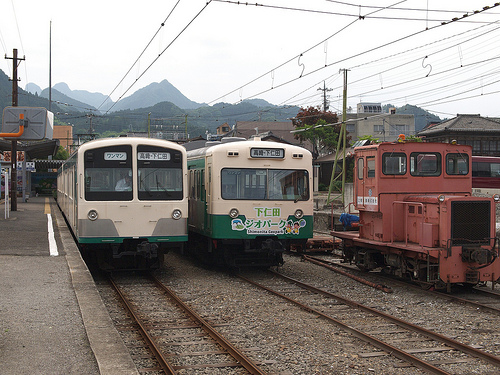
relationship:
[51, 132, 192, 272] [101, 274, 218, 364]
rail car on tracks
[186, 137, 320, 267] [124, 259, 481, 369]
rail car on tracks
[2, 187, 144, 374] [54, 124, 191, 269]
platform beside train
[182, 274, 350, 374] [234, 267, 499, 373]
gravel beside tracks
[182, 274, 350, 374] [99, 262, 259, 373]
gravel beside tracks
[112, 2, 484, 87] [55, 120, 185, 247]
power cables above train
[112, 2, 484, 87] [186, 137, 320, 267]
power cables above rail car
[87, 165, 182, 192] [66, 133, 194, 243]
windshield on train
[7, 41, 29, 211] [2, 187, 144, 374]
pole on platform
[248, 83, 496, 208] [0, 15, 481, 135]
buildings in background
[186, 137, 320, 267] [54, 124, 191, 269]
rail car at a train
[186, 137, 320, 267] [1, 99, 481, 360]
rail car at a train station